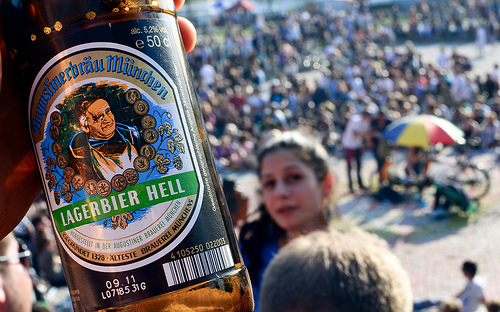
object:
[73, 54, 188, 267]
beer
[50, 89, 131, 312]
close up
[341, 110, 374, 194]
man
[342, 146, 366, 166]
shorts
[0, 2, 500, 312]
camera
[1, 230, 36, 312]
man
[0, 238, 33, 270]
glasses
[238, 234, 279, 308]
shirt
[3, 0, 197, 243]
hand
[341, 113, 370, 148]
shirt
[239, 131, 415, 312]
girl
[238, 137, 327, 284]
hair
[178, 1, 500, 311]
crowd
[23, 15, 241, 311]
label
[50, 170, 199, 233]
stripe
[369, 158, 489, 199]
bicycle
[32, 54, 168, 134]
writing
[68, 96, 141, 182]
male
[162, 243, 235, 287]
barcode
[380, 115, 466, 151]
umbrella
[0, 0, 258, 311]
beer bottle